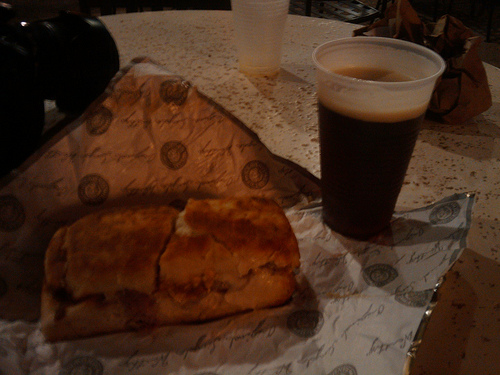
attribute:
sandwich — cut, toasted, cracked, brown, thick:
[37, 201, 304, 334]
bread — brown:
[31, 192, 300, 337]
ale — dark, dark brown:
[314, 94, 425, 242]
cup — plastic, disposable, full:
[310, 34, 446, 244]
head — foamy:
[322, 62, 435, 127]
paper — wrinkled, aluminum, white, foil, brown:
[4, 57, 483, 375]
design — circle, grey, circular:
[54, 81, 276, 197]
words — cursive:
[363, 326, 414, 361]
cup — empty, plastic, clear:
[235, 0, 282, 73]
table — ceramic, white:
[2, 7, 499, 374]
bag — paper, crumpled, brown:
[361, 1, 500, 121]